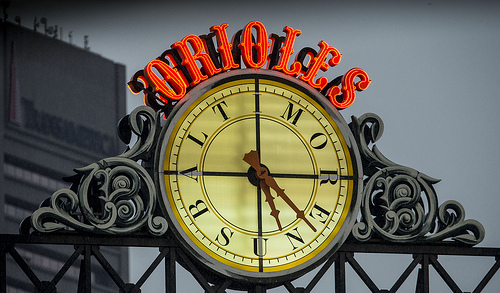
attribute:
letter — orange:
[145, 57, 185, 102]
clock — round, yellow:
[140, 67, 365, 286]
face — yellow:
[165, 78, 353, 270]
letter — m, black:
[281, 100, 304, 125]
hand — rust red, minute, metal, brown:
[241, 148, 316, 231]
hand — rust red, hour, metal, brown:
[260, 181, 282, 233]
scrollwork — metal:
[347, 111, 487, 246]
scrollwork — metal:
[16, 108, 169, 239]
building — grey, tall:
[2, 19, 132, 292]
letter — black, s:
[215, 223, 236, 250]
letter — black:
[184, 129, 208, 146]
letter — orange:
[328, 66, 371, 110]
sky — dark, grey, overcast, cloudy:
[2, 0, 500, 291]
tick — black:
[264, 86, 269, 94]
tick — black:
[317, 116, 324, 124]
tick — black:
[224, 249, 228, 256]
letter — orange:
[239, 20, 268, 70]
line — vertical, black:
[253, 77, 268, 272]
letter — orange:
[171, 32, 221, 86]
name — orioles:
[144, 20, 371, 111]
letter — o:
[309, 131, 330, 149]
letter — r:
[317, 166, 341, 187]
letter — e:
[309, 200, 332, 224]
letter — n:
[284, 224, 307, 249]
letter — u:
[251, 235, 268, 257]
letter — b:
[185, 199, 209, 220]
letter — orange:
[299, 38, 339, 90]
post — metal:
[333, 252, 346, 292]